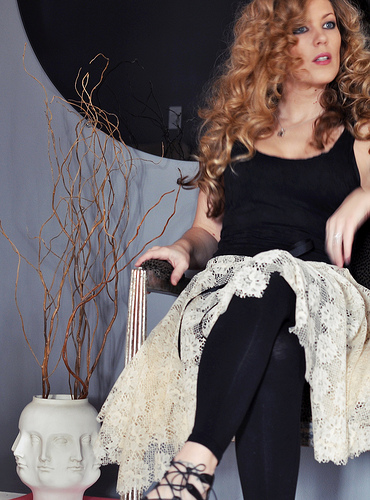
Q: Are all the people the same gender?
A: Yes, all the people are female.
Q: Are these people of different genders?
A: No, all the people are female.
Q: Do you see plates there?
A: No, there are no plates.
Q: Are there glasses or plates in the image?
A: No, there are no plates or glasses.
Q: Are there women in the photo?
A: Yes, there is a woman.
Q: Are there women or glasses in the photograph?
A: Yes, there is a woman.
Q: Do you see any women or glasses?
A: Yes, there is a woman.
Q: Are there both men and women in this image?
A: No, there is a woman but no men.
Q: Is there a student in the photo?
A: No, there are no students.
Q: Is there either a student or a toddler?
A: No, there are no students or toddlers.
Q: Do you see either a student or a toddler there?
A: No, there are no students or toddlers.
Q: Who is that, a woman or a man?
A: That is a woman.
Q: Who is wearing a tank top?
A: The woman is wearing a tank top.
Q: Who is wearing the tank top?
A: The woman is wearing a tank top.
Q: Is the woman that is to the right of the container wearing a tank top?
A: Yes, the woman is wearing a tank top.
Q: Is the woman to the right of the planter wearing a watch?
A: No, the woman is wearing a tank top.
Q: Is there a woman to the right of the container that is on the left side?
A: Yes, there is a woman to the right of the container.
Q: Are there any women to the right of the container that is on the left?
A: Yes, there is a woman to the right of the container.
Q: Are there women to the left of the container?
A: No, the woman is to the right of the container.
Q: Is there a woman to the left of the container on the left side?
A: No, the woman is to the right of the container.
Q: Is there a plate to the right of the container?
A: No, there is a woman to the right of the container.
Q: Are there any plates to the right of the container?
A: No, there is a woman to the right of the container.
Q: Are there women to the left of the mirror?
A: No, the woman is to the right of the mirror.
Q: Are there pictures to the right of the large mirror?
A: No, there is a woman to the right of the mirror.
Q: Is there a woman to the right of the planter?
A: Yes, there is a woman to the right of the planter.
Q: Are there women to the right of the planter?
A: Yes, there is a woman to the right of the planter.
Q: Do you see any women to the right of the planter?
A: Yes, there is a woman to the right of the planter.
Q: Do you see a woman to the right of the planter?
A: Yes, there is a woman to the right of the planter.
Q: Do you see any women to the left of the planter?
A: No, the woman is to the right of the planter.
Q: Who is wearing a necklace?
A: The woman is wearing a necklace.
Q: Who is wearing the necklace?
A: The woman is wearing a necklace.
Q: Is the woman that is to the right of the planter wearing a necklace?
A: Yes, the woman is wearing a necklace.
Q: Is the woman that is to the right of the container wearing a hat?
A: No, the woman is wearing a necklace.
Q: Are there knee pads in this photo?
A: No, there are no knee pads.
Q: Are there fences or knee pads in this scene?
A: No, there are no knee pads or fences.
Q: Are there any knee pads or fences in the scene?
A: No, there are no knee pads or fences.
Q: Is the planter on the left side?
A: Yes, the planter is on the left of the image.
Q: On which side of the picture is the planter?
A: The planter is on the left of the image.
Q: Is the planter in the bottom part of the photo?
A: Yes, the planter is in the bottom of the image.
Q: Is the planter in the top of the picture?
A: No, the planter is in the bottom of the image.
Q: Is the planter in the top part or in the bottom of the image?
A: The planter is in the bottom of the image.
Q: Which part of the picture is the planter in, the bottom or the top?
A: The planter is in the bottom of the image.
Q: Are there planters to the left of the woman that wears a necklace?
A: Yes, there is a planter to the left of the woman.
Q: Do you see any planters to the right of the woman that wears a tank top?
A: No, the planter is to the left of the woman.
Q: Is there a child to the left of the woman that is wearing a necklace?
A: No, there is a planter to the left of the woman.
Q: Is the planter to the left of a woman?
A: Yes, the planter is to the left of a woman.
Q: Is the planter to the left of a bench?
A: No, the planter is to the left of a woman.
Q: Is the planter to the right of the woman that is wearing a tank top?
A: No, the planter is to the left of the woman.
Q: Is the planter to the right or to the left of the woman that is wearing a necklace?
A: The planter is to the left of the woman.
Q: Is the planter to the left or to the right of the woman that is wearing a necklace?
A: The planter is to the left of the woman.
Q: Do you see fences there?
A: No, there are no fences.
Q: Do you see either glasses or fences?
A: No, there are no fences or glasses.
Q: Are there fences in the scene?
A: No, there are no fences.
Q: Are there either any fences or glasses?
A: No, there are no fences or glasses.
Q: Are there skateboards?
A: No, there are no skateboards.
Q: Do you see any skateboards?
A: No, there are no skateboards.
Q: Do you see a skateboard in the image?
A: No, there are no skateboards.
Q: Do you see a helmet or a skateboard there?
A: No, there are no skateboards or helmets.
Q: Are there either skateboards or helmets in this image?
A: No, there are no skateboards or helmets.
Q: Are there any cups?
A: No, there are no cups.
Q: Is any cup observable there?
A: No, there are no cups.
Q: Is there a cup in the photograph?
A: No, there are no cups.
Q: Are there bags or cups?
A: No, there are no cups or bags.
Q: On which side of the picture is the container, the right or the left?
A: The container is on the left of the image.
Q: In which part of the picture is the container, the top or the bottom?
A: The container is in the bottom of the image.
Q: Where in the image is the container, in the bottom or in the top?
A: The container is in the bottom of the image.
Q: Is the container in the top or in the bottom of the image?
A: The container is in the bottom of the image.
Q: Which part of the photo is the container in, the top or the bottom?
A: The container is in the bottom of the image.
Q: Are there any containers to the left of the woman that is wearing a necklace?
A: Yes, there is a container to the left of the woman.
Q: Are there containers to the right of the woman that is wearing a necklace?
A: No, the container is to the left of the woman.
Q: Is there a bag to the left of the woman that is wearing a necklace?
A: No, there is a container to the left of the woman.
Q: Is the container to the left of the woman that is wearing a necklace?
A: Yes, the container is to the left of the woman.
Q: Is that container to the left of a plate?
A: No, the container is to the left of the woman.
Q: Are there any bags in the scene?
A: No, there are no bags.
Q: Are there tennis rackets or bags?
A: No, there are no bags or tennis rackets.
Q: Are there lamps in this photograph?
A: No, there are no lamps.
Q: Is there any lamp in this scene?
A: No, there are no lamps.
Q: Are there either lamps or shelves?
A: No, there are no lamps or shelves.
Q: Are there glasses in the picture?
A: No, there are no glasses.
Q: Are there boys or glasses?
A: No, there are no glasses or boys.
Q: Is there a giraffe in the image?
A: No, there are no giraffes.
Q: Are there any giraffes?
A: No, there are no giraffes.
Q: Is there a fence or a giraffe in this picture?
A: No, there are no giraffes or fences.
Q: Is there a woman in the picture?
A: Yes, there is a woman.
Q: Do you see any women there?
A: Yes, there is a woman.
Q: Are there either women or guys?
A: Yes, there is a woman.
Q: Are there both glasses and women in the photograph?
A: No, there is a woman but no glasses.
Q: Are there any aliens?
A: No, there are no aliens.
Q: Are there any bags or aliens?
A: No, there are no aliens or bags.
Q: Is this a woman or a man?
A: This is a woman.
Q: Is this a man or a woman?
A: This is a woman.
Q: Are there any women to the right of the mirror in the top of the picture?
A: Yes, there is a woman to the right of the mirror.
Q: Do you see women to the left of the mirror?
A: No, the woman is to the right of the mirror.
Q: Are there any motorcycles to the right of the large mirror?
A: No, there is a woman to the right of the mirror.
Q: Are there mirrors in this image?
A: Yes, there is a mirror.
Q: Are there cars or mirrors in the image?
A: Yes, there is a mirror.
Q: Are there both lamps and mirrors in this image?
A: No, there is a mirror but no lamps.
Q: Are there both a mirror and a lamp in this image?
A: No, there is a mirror but no lamps.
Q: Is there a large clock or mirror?
A: Yes, there is a large mirror.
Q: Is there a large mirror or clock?
A: Yes, there is a large mirror.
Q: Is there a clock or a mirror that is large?
A: Yes, the mirror is large.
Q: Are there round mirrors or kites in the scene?
A: Yes, there is a round mirror.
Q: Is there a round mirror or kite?
A: Yes, there is a round mirror.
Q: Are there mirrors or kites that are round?
A: Yes, the mirror is round.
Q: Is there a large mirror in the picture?
A: Yes, there is a large mirror.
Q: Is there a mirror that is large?
A: Yes, there is a mirror that is large.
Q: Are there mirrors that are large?
A: Yes, there is a mirror that is large.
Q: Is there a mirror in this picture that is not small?
A: Yes, there is a large mirror.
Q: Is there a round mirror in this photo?
A: Yes, there is a round mirror.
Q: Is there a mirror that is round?
A: Yes, there is a mirror that is round.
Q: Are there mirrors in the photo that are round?
A: Yes, there is a mirror that is round.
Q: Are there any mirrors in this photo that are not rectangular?
A: Yes, there is a round mirror.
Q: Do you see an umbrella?
A: No, there are no umbrellas.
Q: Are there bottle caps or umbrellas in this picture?
A: No, there are no umbrellas or bottle caps.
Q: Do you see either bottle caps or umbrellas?
A: No, there are no umbrellas or bottle caps.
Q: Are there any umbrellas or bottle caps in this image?
A: No, there are no umbrellas or bottle caps.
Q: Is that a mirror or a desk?
A: That is a mirror.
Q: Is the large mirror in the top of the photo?
A: Yes, the mirror is in the top of the image.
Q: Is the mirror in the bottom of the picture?
A: No, the mirror is in the top of the image.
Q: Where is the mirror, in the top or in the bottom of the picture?
A: The mirror is in the top of the image.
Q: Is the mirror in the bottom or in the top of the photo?
A: The mirror is in the top of the image.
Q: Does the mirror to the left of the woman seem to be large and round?
A: Yes, the mirror is large and round.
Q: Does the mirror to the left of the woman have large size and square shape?
A: No, the mirror is large but round.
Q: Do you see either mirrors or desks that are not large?
A: No, there is a mirror but it is large.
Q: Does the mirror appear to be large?
A: Yes, the mirror is large.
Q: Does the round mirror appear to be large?
A: Yes, the mirror is large.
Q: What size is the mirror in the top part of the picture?
A: The mirror is large.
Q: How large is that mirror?
A: The mirror is large.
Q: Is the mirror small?
A: No, the mirror is large.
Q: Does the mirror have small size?
A: No, the mirror is large.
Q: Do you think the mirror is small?
A: No, the mirror is large.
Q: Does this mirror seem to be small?
A: No, the mirror is large.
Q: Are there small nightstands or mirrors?
A: No, there is a mirror but it is large.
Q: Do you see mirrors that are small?
A: No, there is a mirror but it is large.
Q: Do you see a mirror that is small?
A: No, there is a mirror but it is large.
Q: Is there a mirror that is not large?
A: No, there is a mirror but it is large.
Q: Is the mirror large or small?
A: The mirror is large.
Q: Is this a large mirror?
A: Yes, this is a large mirror.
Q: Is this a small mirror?
A: No, this is a large mirror.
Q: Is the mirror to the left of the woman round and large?
A: Yes, the mirror is round and large.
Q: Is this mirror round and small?
A: No, the mirror is round but large.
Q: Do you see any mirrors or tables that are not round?
A: No, there is a mirror but it is round.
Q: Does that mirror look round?
A: Yes, the mirror is round.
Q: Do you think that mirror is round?
A: Yes, the mirror is round.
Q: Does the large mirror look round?
A: Yes, the mirror is round.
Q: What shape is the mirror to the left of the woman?
A: The mirror is round.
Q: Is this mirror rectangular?
A: No, the mirror is round.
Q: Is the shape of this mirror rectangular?
A: No, the mirror is round.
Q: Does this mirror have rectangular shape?
A: No, the mirror is round.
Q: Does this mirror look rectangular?
A: No, the mirror is round.